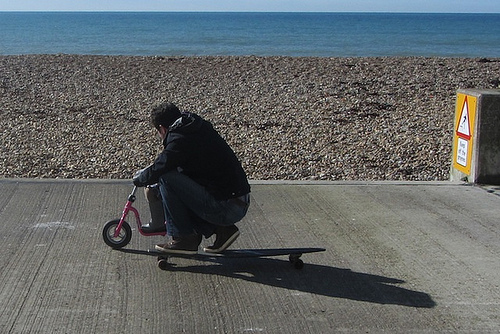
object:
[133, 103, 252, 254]
man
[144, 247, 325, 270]
skateboard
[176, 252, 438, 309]
shadow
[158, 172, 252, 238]
jeans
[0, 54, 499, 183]
beach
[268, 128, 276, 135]
pebbles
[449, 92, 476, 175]
sign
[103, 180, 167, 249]
scooter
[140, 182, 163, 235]
child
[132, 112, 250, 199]
jacket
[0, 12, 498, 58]
water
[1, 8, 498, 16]
horizon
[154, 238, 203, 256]
shoes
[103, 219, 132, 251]
tire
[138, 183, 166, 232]
leg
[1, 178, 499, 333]
concrete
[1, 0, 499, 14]
sky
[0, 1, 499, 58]
blue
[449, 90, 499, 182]
post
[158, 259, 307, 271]
wheels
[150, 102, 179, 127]
hair